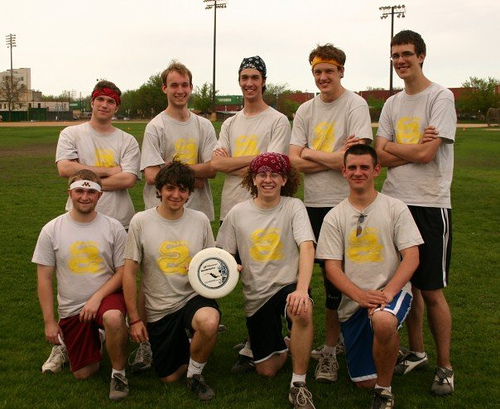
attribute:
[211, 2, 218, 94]
pole — metal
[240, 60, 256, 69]
band — white, red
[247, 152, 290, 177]
bandana — red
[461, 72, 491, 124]
tree — short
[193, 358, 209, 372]
socks — white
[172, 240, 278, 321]
frisbee — round, white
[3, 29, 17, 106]
pole — tall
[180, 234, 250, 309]
frisbee — white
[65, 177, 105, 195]
sweatband — white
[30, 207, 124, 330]
t-shirt — white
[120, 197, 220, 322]
t-shirt — white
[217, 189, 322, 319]
t-shirt — white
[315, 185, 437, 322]
t-shirt — white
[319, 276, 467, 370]
shorts — blue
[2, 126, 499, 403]
field — grassy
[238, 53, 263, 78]
bandana — red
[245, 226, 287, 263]
writing — yellow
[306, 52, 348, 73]
headband — yellow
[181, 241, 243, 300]
frisbee — white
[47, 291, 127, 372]
shorts — red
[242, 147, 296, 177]
scarf — red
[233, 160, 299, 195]
hair — curly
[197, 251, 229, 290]
markings — black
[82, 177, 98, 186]
letter — red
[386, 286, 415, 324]
stripes — white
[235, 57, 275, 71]
bandana — green